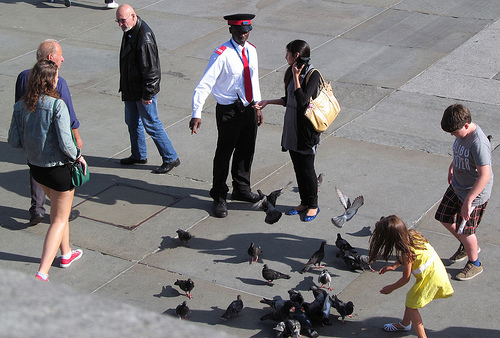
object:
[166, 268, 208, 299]
birds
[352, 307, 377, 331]
food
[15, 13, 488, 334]
daytime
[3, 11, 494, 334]
city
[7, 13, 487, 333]
day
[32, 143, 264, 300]
sunshine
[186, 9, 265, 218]
man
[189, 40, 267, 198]
uniform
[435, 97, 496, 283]
children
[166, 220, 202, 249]
birds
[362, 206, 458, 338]
girl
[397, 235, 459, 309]
yellow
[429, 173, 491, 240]
shorts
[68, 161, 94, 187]
clutch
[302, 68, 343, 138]
pocket book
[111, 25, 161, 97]
jacket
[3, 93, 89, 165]
jacket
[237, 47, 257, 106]
tie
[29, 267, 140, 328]
pavement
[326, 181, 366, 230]
bird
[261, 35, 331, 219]
woman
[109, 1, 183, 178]
person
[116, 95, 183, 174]
legs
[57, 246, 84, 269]
shoe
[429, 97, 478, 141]
head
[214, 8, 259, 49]
head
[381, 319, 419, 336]
sandals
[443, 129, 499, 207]
grey shirt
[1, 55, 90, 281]
woman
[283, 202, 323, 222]
sandals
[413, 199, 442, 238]
down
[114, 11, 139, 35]
facial hair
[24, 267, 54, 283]
shoes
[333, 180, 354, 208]
wings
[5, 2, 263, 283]
people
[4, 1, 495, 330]
people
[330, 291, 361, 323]
pigeons